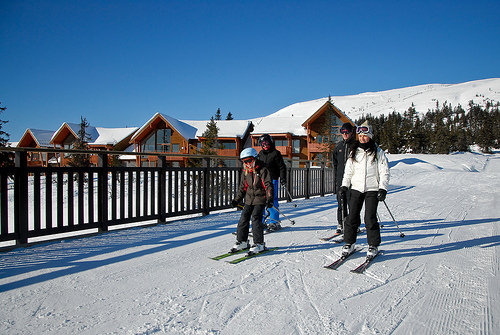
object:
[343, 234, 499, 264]
shadow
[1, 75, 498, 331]
snow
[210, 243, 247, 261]
board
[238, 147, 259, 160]
helmet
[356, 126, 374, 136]
goggles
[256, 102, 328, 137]
roof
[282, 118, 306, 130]
snow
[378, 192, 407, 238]
pole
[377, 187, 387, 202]
hand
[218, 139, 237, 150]
window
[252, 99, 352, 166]
house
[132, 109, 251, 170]
house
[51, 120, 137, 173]
house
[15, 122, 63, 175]
house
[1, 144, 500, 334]
snow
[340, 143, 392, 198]
jacket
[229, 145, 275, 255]
guy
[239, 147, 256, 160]
blue helmet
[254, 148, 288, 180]
jacket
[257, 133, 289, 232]
person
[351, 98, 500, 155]
trees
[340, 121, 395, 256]
skiers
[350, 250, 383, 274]
board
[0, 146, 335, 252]
wooden fence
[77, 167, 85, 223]
fence board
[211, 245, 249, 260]
green ski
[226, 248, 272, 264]
green ski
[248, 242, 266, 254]
foot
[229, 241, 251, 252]
foot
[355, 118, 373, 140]
hat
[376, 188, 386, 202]
glove